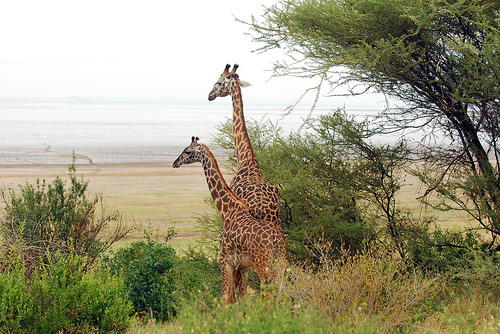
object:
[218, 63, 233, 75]
horns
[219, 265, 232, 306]
leg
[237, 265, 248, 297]
leg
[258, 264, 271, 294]
leg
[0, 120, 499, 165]
water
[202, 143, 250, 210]
mane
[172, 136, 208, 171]
head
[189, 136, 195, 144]
horns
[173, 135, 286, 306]
animal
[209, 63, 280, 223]
animal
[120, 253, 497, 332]
grass